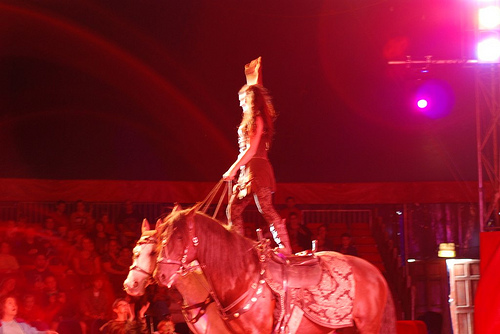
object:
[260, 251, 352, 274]
back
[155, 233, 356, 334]
tack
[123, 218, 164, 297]
bridle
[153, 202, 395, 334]
horse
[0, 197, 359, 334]
audience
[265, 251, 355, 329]
blanket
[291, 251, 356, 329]
pattern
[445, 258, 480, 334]
door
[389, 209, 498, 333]
background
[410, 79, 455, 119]
spotlight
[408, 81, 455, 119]
halo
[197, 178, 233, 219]
reins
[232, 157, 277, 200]
skirt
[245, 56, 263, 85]
hand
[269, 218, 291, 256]
boots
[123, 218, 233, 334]
horse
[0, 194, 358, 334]
stands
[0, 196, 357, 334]
people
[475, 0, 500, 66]
lights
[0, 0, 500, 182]
ceiling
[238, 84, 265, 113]
head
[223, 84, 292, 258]
person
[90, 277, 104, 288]
head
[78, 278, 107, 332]
person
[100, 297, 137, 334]
person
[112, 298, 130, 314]
head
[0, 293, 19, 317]
head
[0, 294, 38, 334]
person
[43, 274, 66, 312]
person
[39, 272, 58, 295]
head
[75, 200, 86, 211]
head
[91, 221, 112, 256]
person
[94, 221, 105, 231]
head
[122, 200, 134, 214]
head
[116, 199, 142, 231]
person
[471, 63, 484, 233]
metal frame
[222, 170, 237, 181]
hands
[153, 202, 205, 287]
bridle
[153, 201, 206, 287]
head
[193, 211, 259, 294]
mane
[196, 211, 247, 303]
neck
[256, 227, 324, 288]
saddle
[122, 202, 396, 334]
showhorse